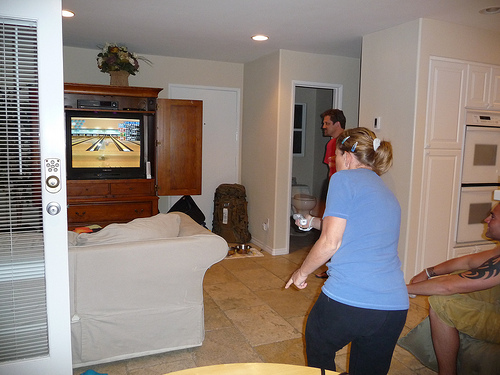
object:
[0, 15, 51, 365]
mini blinds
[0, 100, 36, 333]
glass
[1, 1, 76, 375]
door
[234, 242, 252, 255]
bowl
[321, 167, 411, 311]
blue top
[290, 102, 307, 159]
window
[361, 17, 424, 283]
wall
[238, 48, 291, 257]
wall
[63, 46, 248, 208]
wall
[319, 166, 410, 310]
shirt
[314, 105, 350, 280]
man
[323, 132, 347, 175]
shirt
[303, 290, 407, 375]
pants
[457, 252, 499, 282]
tattoo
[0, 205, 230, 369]
couch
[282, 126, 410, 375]
lady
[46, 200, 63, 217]
door knob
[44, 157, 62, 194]
door lock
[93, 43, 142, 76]
flowers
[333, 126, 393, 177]
hair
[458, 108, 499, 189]
oven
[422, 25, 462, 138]
wall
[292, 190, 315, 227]
toilet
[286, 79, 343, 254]
bathroom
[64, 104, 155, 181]
television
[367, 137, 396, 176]
pony tail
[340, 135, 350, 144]
barrett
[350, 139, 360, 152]
barrett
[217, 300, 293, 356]
tile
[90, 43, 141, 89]
flower basket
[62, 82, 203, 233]
television stand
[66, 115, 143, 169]
bowling alley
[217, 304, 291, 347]
floor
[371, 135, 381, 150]
band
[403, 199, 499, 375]
man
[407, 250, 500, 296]
arm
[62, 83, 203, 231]
cabinet